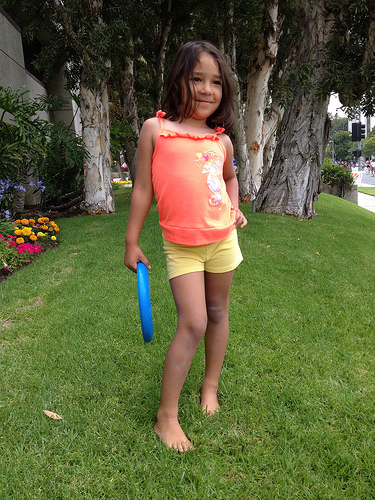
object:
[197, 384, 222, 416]
foot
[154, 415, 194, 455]
foot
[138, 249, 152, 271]
thumb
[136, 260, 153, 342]
frisbee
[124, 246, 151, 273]
hand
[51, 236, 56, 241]
yellow flowers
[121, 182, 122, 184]
yellow flowers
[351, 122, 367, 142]
light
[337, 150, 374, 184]
street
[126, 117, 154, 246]
arm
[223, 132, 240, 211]
arm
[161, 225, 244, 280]
shorts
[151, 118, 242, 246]
tank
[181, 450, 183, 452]
toe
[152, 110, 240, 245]
shirt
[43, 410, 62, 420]
leaf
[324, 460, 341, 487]
grass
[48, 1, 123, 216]
tree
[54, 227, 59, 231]
orange flower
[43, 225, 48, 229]
orange flower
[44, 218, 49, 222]
orange flower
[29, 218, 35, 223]
orange flower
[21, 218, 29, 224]
orange flower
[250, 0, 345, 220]
tree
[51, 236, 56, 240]
flowers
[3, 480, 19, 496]
grass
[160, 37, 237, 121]
head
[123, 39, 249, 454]
girl